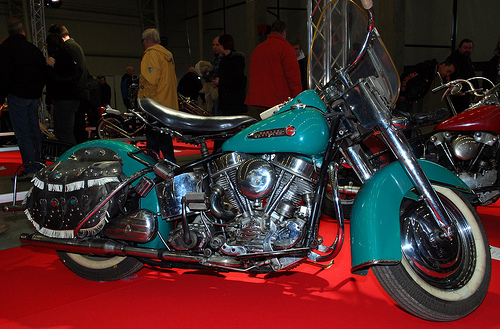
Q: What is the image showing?
A: It is showing a display.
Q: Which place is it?
A: It is a display.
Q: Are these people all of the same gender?
A: No, they are both male and female.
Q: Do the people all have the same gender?
A: No, they are both male and female.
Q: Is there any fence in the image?
A: No, there are no fences.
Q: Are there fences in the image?
A: No, there are no fences.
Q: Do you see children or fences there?
A: No, there are no fences or children.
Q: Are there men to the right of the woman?
A: Yes, there is a man to the right of the woman.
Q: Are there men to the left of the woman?
A: No, the man is to the right of the woman.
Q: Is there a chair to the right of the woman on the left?
A: No, there is a man to the right of the woman.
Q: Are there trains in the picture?
A: No, there are no trains.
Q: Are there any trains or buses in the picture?
A: No, there are no trains or buses.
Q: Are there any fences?
A: No, there are no fences.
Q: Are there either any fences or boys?
A: No, there are no fences or boys.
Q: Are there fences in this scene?
A: No, there are no fences.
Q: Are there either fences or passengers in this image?
A: No, there are no fences or passengers.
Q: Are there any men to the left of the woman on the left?
A: No, the man is to the right of the woman.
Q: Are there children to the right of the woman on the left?
A: No, there is a man to the right of the woman.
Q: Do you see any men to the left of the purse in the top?
A: No, the man is to the right of the purse.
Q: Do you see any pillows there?
A: No, there are no pillows.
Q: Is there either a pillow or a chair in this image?
A: No, there are no pillows or chairs.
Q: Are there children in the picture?
A: No, there are no children.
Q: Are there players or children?
A: No, there are no children or players.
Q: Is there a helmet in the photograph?
A: No, there are no helmets.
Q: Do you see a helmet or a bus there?
A: No, there are no helmets or buses.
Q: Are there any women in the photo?
A: Yes, there is a woman.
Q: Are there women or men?
A: Yes, there is a woman.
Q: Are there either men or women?
A: Yes, there is a woman.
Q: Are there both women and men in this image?
A: Yes, there are both a woman and a man.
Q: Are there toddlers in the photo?
A: No, there are no toddlers.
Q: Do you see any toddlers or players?
A: No, there are no toddlers or players.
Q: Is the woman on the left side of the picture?
A: Yes, the woman is on the left of the image.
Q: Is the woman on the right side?
A: No, the woman is on the left of the image.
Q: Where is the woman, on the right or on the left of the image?
A: The woman is on the left of the image.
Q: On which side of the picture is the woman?
A: The woman is on the left of the image.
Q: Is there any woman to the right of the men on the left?
A: Yes, there is a woman to the right of the men.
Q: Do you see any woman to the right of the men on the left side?
A: Yes, there is a woman to the right of the men.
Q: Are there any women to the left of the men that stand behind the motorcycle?
A: No, the woman is to the right of the men.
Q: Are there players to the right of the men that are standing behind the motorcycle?
A: No, there is a woman to the right of the men.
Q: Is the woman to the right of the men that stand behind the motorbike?
A: Yes, the woman is to the right of the men.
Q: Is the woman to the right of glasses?
A: No, the woman is to the right of the men.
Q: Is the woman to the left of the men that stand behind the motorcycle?
A: No, the woman is to the right of the men.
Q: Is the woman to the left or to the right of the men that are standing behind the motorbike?
A: The woman is to the right of the men.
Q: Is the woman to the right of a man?
A: No, the woman is to the left of a man.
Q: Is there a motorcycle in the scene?
A: Yes, there is a motorcycle.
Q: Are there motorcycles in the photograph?
A: Yes, there is a motorcycle.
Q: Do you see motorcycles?
A: Yes, there is a motorcycle.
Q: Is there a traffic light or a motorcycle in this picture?
A: Yes, there is a motorcycle.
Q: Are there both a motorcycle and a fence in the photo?
A: No, there is a motorcycle but no fences.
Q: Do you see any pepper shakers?
A: No, there are no pepper shakers.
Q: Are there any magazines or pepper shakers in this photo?
A: No, there are no pepper shakers or magazines.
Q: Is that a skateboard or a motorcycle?
A: That is a motorcycle.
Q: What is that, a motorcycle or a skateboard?
A: That is a motorcycle.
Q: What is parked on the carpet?
A: The motorcycle is parked on the carpet.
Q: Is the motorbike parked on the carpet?
A: Yes, the motorbike is parked on the carpet.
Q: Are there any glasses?
A: No, there are no glasses.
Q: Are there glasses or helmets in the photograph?
A: No, there are no glasses or helmets.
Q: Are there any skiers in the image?
A: No, there are no skiers.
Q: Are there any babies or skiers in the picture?
A: No, there are no skiers or babies.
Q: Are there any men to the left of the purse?
A: Yes, there are men to the left of the purse.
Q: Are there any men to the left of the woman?
A: Yes, there are men to the left of the woman.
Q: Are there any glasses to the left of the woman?
A: No, there are men to the left of the woman.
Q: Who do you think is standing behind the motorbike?
A: The men are standing behind the motorbike.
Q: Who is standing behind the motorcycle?
A: The men are standing behind the motorbike.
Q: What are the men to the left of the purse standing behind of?
A: The men are standing behind the motorbike.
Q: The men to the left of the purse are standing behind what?
A: The men are standing behind the motorbike.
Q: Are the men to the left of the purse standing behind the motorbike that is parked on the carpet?
A: Yes, the men are standing behind the motorbike.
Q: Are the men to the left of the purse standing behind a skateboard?
A: No, the men are standing behind the motorbike.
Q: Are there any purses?
A: Yes, there is a purse.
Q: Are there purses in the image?
A: Yes, there is a purse.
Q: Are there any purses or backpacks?
A: Yes, there is a purse.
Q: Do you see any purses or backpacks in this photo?
A: Yes, there is a purse.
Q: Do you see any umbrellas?
A: No, there are no umbrellas.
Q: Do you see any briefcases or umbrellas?
A: No, there are no umbrellas or briefcases.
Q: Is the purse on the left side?
A: Yes, the purse is on the left of the image.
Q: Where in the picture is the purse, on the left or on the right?
A: The purse is on the left of the image.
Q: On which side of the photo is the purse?
A: The purse is on the left of the image.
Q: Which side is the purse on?
A: The purse is on the left of the image.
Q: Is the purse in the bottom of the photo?
A: No, the purse is in the top of the image.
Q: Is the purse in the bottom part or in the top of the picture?
A: The purse is in the top of the image.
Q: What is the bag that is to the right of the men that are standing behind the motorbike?
A: The bag is a purse.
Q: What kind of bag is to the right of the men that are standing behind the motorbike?
A: The bag is a purse.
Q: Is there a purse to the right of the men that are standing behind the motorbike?
A: Yes, there is a purse to the right of the men.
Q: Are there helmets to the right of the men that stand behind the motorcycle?
A: No, there is a purse to the right of the men.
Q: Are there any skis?
A: No, there are no skis.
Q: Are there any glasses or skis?
A: No, there are no skis or glasses.